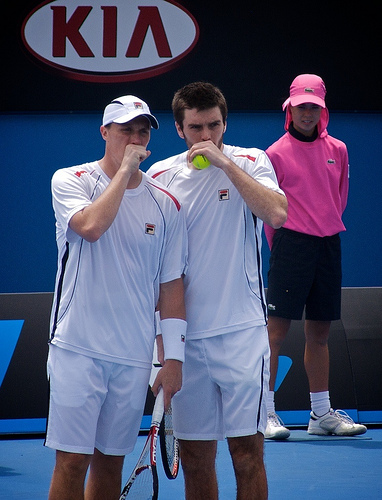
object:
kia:
[40, 1, 173, 61]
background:
[0, 0, 381, 499]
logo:
[22, 2, 200, 87]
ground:
[0, 425, 381, 500]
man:
[42, 89, 190, 498]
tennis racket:
[118, 384, 165, 500]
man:
[144, 76, 288, 500]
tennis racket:
[158, 388, 184, 482]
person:
[257, 70, 366, 444]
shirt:
[261, 130, 350, 251]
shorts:
[41, 344, 152, 459]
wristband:
[159, 317, 189, 368]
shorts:
[262, 225, 346, 325]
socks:
[306, 389, 332, 417]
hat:
[101, 94, 160, 130]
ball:
[191, 151, 211, 171]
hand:
[121, 143, 150, 171]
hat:
[281, 74, 331, 142]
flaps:
[279, 98, 331, 140]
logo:
[326, 158, 337, 165]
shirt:
[46, 160, 191, 371]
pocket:
[49, 350, 91, 407]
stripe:
[50, 242, 71, 342]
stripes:
[143, 174, 182, 213]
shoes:
[305, 406, 368, 439]